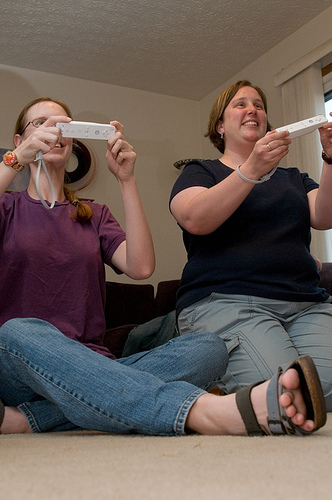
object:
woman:
[0, 97, 328, 438]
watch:
[2, 149, 24, 175]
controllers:
[273, 111, 327, 145]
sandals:
[230, 354, 327, 436]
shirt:
[0, 189, 127, 360]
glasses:
[18, 118, 50, 133]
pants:
[176, 292, 331, 418]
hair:
[14, 98, 93, 228]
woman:
[167, 79, 331, 420]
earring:
[217, 132, 226, 141]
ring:
[266, 148, 273, 153]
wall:
[0, 65, 205, 297]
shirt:
[168, 158, 329, 336]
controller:
[51, 121, 114, 144]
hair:
[204, 80, 272, 156]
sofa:
[103, 281, 156, 346]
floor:
[0, 409, 331, 499]